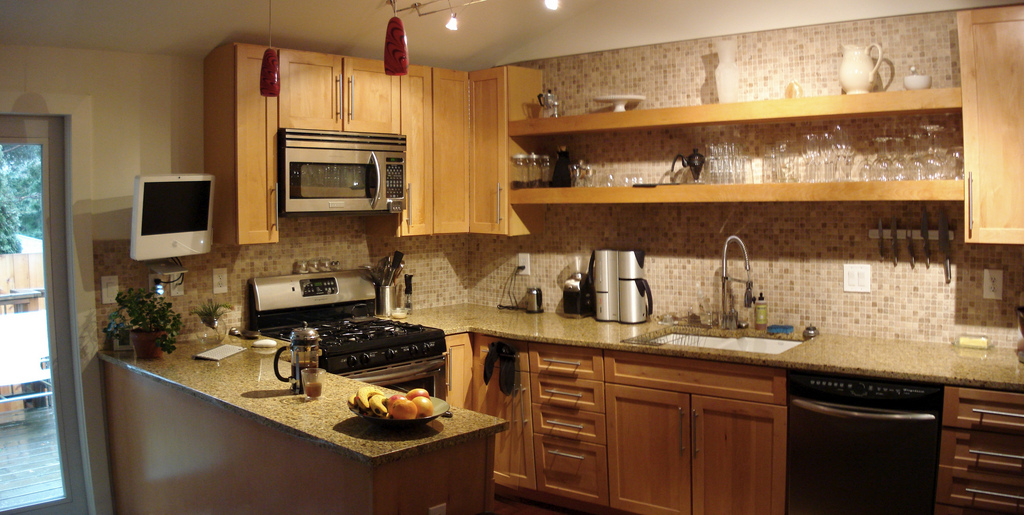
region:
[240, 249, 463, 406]
the stove is silver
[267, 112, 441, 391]
a microwave above a stove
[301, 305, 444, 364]
black burners of a stove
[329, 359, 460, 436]
fruits on a bowl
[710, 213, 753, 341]
the faucet is color silver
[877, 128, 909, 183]
the glass on a shelf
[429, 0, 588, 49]
lights on the ceiling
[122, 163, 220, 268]
one flat panel white monitor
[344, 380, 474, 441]
bowl of fruit on kitchen counter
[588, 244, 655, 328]
one black and white coffee maker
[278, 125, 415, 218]
one black and stainless steel microwave oven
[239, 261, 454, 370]
one black and stainless steel gas stovetop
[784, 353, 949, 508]
one black dishwasher with silver handle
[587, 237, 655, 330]
Kettle on counter top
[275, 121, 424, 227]
Microwave sandwiched between wooden drawers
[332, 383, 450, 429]
Bananas and oranges on wide plate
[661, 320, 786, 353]
White colored kitchen sink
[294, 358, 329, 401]
Juice in small glass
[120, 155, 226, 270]
Screen mounted on wall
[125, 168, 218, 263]
monitor is attached to wall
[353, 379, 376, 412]
banana sits in bowl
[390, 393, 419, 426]
orange sits in bowl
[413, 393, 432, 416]
orange sits in bowl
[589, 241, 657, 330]
coffee pot sits on kitchen counter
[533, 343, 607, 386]
kitchen drawer is closed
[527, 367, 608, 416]
kitchen drawer is closed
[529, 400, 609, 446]
kitchen drawer is closed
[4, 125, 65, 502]
a door in the room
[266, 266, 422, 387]
a stove in the kitchen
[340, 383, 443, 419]
a bowl of fruit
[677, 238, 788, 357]
a sink on the counter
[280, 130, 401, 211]
a silver microwave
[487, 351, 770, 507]
wooden cabinets under the sink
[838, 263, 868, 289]
a light switch on the wall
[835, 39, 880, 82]
a white vase on a shelf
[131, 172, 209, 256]
a white television on the wall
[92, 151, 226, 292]
television on the wall in the kitchen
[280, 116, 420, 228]
built in microwave above the stove in the kitchen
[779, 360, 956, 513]
built in dishwasher in the kitchen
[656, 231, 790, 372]
Large faucet in the kitchen over the sink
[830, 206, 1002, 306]
Magnetic knife rack above the counter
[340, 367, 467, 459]
fruit in a basket on the edge of the counter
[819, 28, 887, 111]
Pitcher on the top of the shelf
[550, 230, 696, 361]
coffee maker on the counter above the drawers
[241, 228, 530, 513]
stove and oven underneath the microwave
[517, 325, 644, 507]
drawers underneath the counter in the kitchen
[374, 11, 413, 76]
red lamp shade above counter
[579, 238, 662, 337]
silver coffee maker on counter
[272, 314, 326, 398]
coffee mug on counter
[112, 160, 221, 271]
small television screen mounted on wall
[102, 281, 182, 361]
small plant on counter